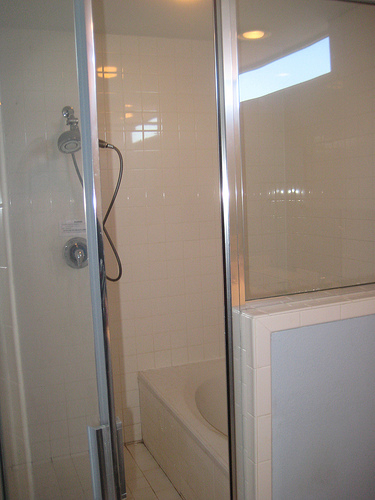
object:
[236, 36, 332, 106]
window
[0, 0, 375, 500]
bathroom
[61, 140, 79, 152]
nozzle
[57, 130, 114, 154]
shower head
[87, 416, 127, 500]
handle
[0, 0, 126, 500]
door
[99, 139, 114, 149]
handle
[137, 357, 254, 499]
bath tub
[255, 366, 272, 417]
tile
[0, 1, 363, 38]
ceiling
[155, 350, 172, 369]
tile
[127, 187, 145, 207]
tile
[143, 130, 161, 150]
tile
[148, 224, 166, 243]
tile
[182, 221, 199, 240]
tile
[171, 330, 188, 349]
tile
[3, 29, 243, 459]
shower wall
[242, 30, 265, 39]
ceiling light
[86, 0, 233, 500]
door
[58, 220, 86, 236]
sticker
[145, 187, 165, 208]
tile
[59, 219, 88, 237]
tag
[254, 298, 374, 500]
wall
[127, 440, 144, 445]
grout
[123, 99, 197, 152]
repetition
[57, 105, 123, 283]
shower